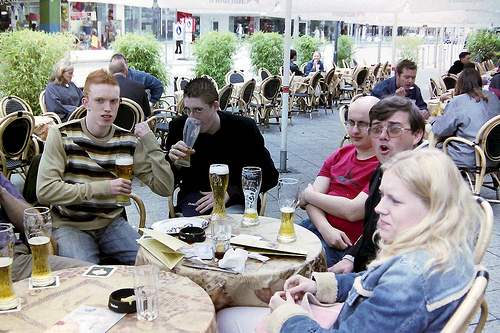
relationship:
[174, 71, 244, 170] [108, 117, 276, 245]
man drinking beer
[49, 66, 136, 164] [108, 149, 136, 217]
boy holding glass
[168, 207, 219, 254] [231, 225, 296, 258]
ashtray on table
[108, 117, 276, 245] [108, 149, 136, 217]
beer in glass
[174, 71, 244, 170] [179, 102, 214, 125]
man wearing eyeglasses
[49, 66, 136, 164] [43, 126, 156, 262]
boy wearing sweater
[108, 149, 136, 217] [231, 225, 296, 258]
glass on table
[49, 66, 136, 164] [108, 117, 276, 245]
boy with beer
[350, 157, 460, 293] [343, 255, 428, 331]
girl wearing jacket